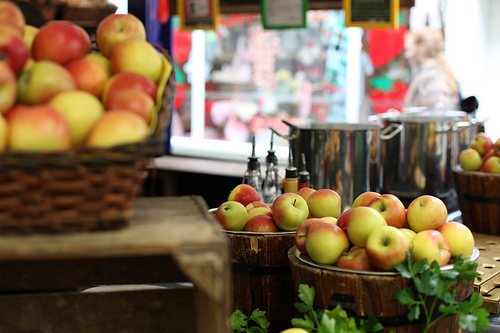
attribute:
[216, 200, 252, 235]
apple — yellow, red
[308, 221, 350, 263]
apple — yellow, red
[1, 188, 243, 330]
bench — wooden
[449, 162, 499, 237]
basket — wooden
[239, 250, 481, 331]
plants — small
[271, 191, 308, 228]
apple — red, yellow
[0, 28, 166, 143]
apples — ripe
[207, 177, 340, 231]
apples — ripe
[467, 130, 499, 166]
apples — ripe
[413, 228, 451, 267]
apple — red, yellow